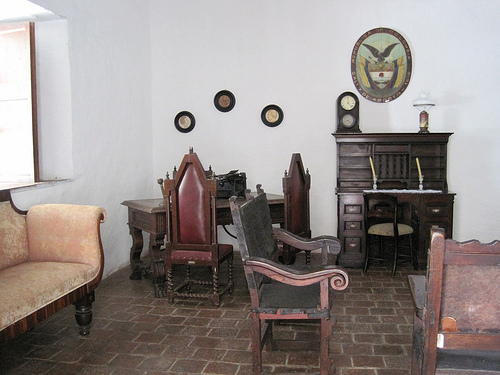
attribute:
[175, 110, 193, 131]
frame — round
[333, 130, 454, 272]
desk — brown, wooden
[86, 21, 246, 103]
wall — white, painted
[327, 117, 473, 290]
desk — wooden , old , dark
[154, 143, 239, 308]
chair — old , wooden 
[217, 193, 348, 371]
chair — older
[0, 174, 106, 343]
sofa — upholstered 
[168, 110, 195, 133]
picture — small, framed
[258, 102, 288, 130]
frame — round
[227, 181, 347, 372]
chair — old, wooden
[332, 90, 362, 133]
clock — small